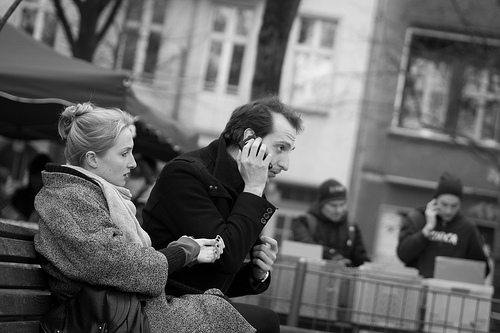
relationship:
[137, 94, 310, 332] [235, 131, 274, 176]
man on phone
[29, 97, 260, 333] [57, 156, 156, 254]
woman wearing scarf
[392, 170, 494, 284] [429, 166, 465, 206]
man wearing hat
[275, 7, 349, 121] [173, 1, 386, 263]
window on building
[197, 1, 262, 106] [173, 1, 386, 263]
window on building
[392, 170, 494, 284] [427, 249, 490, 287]
man looking at laptop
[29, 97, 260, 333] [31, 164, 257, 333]
woman in clothing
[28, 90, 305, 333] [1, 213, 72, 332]
couple on bench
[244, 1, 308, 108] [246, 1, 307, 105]
tree has trunk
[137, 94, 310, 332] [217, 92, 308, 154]
man has hair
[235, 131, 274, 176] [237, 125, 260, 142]
phone up to ear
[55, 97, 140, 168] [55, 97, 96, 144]
hair in ponytail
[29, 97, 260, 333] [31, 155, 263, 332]
woman in clothing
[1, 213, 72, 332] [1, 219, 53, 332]
bench has slats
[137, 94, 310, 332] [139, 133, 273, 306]
man in coat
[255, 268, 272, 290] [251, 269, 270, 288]
watch on wrist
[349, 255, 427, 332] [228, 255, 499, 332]
bin behind fence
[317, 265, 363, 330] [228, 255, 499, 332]
part of fence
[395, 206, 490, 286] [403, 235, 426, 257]
man has part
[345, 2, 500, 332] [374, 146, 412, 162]
wall has part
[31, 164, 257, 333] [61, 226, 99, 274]
clothing has part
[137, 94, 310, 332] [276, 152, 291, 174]
man has nose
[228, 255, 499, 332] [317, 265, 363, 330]
fence has part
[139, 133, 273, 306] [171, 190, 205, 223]
jacket has part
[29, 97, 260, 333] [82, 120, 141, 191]
woman has face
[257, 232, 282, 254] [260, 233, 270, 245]
finger has part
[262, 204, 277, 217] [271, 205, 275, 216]
button has part